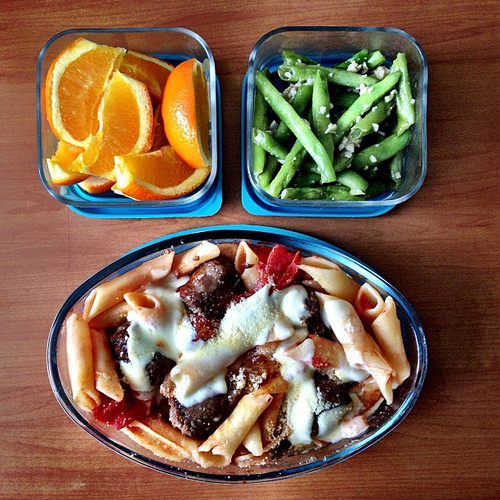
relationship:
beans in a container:
[252, 48, 414, 201] [235, 20, 438, 221]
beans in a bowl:
[252, 50, 418, 199] [246, 25, 428, 209]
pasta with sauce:
[64, 249, 407, 469] [97, 242, 353, 445]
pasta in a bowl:
[66, 240, 409, 469] [45, 224, 427, 485]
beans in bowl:
[252, 48, 414, 201] [235, 19, 429, 214]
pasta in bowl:
[64, 249, 407, 469] [41, 217, 438, 491]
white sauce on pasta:
[120, 281, 352, 428] [62, 237, 424, 468]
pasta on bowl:
[66, 240, 409, 469] [41, 217, 438, 491]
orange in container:
[45, 37, 212, 201] [44, 20, 221, 213]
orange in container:
[47, 31, 117, 146] [44, 20, 221, 213]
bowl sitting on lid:
[246, 25, 428, 209] [238, 49, 397, 217]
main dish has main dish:
[37, 224, 437, 479] [67, 240, 410, 466]